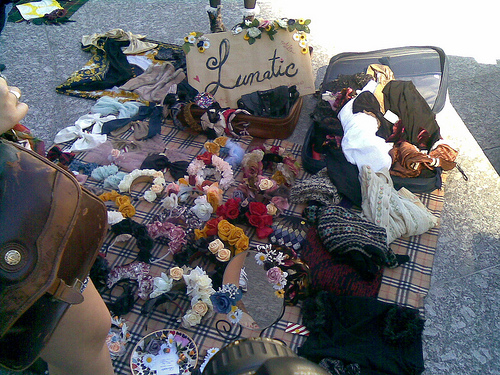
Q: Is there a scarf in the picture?
A: Yes, there is a scarf.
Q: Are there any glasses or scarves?
A: Yes, there is a scarf.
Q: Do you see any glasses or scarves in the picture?
A: Yes, there is a scarf.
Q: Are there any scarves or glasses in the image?
A: Yes, there is a scarf.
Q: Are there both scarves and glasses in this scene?
A: No, there is a scarf but no glasses.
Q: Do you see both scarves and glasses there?
A: No, there is a scarf but no glasses.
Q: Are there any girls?
A: No, there are no girls.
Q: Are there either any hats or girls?
A: No, there are no girls or hats.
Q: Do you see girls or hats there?
A: No, there are no girls or hats.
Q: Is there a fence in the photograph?
A: No, there are no fences.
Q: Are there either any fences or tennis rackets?
A: No, there are no fences or tennis rackets.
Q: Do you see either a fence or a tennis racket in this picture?
A: No, there are no fences or rackets.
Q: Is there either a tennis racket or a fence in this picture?
A: No, there are no fences or rackets.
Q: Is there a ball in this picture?
A: No, there are no balls.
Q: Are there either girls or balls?
A: No, there are no balls or girls.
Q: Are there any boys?
A: No, there are no boys.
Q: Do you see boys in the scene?
A: No, there are no boys.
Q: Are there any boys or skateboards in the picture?
A: No, there are no boys or skateboards.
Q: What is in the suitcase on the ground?
A: The cloths are in the suitcase.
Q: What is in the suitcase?
A: The cloths are in the suitcase.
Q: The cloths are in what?
A: The cloths are in the suitcase.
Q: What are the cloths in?
A: The cloths are in the suitcase.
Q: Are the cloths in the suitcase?
A: Yes, the cloths are in the suitcase.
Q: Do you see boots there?
A: Yes, there are boots.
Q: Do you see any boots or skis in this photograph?
A: Yes, there are boots.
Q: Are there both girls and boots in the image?
A: No, there are boots but no girls.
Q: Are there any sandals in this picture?
A: No, there are no sandals.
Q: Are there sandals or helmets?
A: No, there are no sandals or helmets.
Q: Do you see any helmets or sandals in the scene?
A: No, there are no sandals or helmets.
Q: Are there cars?
A: No, there are no cars.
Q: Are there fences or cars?
A: No, there are no cars or fences.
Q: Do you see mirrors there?
A: Yes, there is a mirror.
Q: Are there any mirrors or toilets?
A: Yes, there is a mirror.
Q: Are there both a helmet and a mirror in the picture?
A: No, there is a mirror but no helmets.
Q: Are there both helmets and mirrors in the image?
A: No, there is a mirror but no helmets.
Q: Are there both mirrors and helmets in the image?
A: No, there is a mirror but no helmets.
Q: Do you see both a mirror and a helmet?
A: No, there is a mirror but no helmets.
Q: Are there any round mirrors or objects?
A: Yes, there is a round mirror.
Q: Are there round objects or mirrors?
A: Yes, there is a round mirror.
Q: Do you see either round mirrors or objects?
A: Yes, there is a round mirror.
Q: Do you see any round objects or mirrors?
A: Yes, there is a round mirror.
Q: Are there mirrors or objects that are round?
A: Yes, the mirror is round.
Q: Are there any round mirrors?
A: Yes, there is a round mirror.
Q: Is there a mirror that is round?
A: Yes, there is a mirror that is round.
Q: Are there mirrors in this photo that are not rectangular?
A: Yes, there is a round mirror.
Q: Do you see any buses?
A: No, there are no buses.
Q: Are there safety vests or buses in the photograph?
A: No, there are no buses or safety vests.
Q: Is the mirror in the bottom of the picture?
A: Yes, the mirror is in the bottom of the image.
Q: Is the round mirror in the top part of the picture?
A: No, the mirror is in the bottom of the image.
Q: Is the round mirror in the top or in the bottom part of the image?
A: The mirror is in the bottom of the image.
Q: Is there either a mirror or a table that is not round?
A: No, there is a mirror but it is round.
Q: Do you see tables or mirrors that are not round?
A: No, there is a mirror but it is round.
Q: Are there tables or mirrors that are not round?
A: No, there is a mirror but it is round.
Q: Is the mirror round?
A: Yes, the mirror is round.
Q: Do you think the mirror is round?
A: Yes, the mirror is round.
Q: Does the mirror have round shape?
A: Yes, the mirror is round.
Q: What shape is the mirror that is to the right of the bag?
A: The mirror is round.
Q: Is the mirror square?
A: No, the mirror is round.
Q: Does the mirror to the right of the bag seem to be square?
A: No, the mirror is round.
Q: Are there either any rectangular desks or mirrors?
A: No, there is a mirror but it is round.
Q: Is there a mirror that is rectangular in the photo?
A: No, there is a mirror but it is round.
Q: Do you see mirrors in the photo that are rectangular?
A: No, there is a mirror but it is round.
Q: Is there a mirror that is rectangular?
A: No, there is a mirror but it is round.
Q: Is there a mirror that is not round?
A: No, there is a mirror but it is round.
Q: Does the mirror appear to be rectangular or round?
A: The mirror is round.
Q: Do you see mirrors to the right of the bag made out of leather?
A: Yes, there is a mirror to the right of the bag.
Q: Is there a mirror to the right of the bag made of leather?
A: Yes, there is a mirror to the right of the bag.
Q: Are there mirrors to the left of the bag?
A: No, the mirror is to the right of the bag.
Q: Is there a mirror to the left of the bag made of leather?
A: No, the mirror is to the right of the bag.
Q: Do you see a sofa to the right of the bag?
A: No, there is a mirror to the right of the bag.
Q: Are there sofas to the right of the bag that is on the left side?
A: No, there is a mirror to the right of the bag.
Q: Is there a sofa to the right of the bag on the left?
A: No, there is a mirror to the right of the bag.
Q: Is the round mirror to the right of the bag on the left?
A: Yes, the mirror is to the right of the bag.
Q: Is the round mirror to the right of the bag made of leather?
A: Yes, the mirror is to the right of the bag.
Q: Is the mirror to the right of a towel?
A: No, the mirror is to the right of the bag.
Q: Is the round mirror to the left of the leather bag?
A: No, the mirror is to the right of the bag.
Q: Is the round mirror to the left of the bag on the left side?
A: No, the mirror is to the right of the bag.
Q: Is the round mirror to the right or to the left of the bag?
A: The mirror is to the right of the bag.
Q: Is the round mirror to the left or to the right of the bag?
A: The mirror is to the right of the bag.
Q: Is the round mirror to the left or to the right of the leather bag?
A: The mirror is to the right of the bag.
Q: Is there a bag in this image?
A: Yes, there is a bag.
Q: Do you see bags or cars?
A: Yes, there is a bag.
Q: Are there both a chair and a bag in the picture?
A: No, there is a bag but no chairs.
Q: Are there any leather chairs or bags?
A: Yes, there is a leather bag.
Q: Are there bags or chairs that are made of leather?
A: Yes, the bag is made of leather.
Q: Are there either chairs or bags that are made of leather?
A: Yes, the bag is made of leather.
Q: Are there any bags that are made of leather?
A: Yes, there is a bag that is made of leather.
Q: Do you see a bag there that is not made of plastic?
A: Yes, there is a bag that is made of leather.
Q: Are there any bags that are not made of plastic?
A: Yes, there is a bag that is made of leather.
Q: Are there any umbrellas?
A: No, there are no umbrellas.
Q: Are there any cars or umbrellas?
A: No, there are no umbrellas or cars.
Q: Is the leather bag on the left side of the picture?
A: Yes, the bag is on the left of the image.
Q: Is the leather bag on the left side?
A: Yes, the bag is on the left of the image.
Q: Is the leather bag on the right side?
A: No, the bag is on the left of the image.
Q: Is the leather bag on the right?
A: No, the bag is on the left of the image.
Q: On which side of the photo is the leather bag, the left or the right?
A: The bag is on the left of the image.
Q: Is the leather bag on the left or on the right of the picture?
A: The bag is on the left of the image.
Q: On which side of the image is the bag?
A: The bag is on the left of the image.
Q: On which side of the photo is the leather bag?
A: The bag is on the left of the image.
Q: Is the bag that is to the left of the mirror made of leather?
A: Yes, the bag is made of leather.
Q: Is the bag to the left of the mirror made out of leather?
A: Yes, the bag is made of leather.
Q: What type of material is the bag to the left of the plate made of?
A: The bag is made of leather.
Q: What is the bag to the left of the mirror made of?
A: The bag is made of leather.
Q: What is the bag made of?
A: The bag is made of leather.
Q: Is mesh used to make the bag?
A: No, the bag is made of leather.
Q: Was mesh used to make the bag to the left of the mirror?
A: No, the bag is made of leather.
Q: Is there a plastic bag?
A: No, there is a bag but it is made of leather.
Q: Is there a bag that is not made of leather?
A: No, there is a bag but it is made of leather.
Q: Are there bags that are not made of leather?
A: No, there is a bag but it is made of leather.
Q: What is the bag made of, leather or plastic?
A: The bag is made of leather.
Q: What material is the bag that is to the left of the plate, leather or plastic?
A: The bag is made of leather.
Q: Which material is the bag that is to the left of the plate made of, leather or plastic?
A: The bag is made of leather.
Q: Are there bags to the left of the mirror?
A: Yes, there is a bag to the left of the mirror.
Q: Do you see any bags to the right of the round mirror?
A: No, the bag is to the left of the mirror.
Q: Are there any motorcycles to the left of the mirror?
A: No, there is a bag to the left of the mirror.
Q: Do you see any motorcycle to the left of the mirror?
A: No, there is a bag to the left of the mirror.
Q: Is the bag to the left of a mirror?
A: Yes, the bag is to the left of a mirror.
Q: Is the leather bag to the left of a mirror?
A: Yes, the bag is to the left of a mirror.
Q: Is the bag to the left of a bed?
A: No, the bag is to the left of a mirror.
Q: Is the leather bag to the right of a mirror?
A: No, the bag is to the left of a mirror.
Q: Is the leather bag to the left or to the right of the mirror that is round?
A: The bag is to the left of the mirror.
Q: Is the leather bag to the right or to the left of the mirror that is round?
A: The bag is to the left of the mirror.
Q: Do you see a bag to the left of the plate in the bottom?
A: Yes, there is a bag to the left of the plate.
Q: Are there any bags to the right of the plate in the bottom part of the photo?
A: No, the bag is to the left of the plate.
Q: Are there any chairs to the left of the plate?
A: No, there is a bag to the left of the plate.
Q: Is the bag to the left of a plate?
A: Yes, the bag is to the left of a plate.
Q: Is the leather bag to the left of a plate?
A: Yes, the bag is to the left of a plate.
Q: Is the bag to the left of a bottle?
A: No, the bag is to the left of a plate.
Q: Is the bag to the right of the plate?
A: No, the bag is to the left of the plate.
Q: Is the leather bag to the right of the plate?
A: No, the bag is to the left of the plate.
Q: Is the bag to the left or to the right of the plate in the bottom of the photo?
A: The bag is to the left of the plate.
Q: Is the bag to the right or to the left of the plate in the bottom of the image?
A: The bag is to the left of the plate.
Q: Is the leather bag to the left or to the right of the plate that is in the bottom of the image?
A: The bag is to the left of the plate.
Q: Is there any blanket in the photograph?
A: Yes, there is a blanket.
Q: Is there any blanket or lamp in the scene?
A: Yes, there is a blanket.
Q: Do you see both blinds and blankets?
A: No, there is a blanket but no blinds.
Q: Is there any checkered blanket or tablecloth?
A: Yes, there is a checkered blanket.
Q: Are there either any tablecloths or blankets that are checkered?
A: Yes, the blanket is checkered.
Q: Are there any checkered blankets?
A: Yes, there is a checkered blanket.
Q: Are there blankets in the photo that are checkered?
A: Yes, there is a blanket that is checkered.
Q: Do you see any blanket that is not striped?
A: Yes, there is a checkered blanket.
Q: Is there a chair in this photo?
A: No, there are no chairs.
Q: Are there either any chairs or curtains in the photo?
A: No, there are no chairs or curtains.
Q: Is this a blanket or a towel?
A: This is a blanket.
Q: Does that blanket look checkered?
A: Yes, the blanket is checkered.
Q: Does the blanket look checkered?
A: Yes, the blanket is checkered.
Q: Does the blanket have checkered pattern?
A: Yes, the blanket is checkered.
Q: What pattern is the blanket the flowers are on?
A: The blanket is checkered.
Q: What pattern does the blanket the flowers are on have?
A: The blanket has checkered pattern.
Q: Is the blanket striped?
A: No, the blanket is checkered.